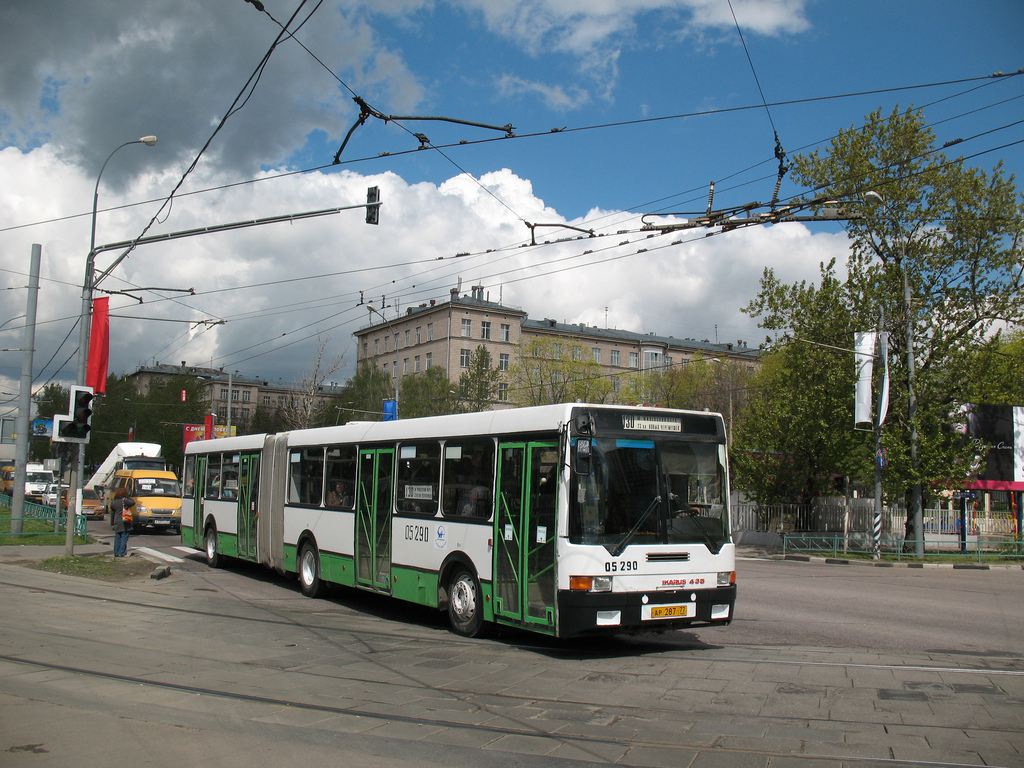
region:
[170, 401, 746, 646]
a long green and white transit bus is driving down the road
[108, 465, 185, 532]
a yellow car is behind the bus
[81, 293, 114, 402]
a red flag is handing off of the pole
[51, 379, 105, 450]
a traffic light is in the shape of an l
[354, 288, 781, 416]
a tan colored building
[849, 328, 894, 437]
a white flag is handing off of the pole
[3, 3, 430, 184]
a blackened storm cloud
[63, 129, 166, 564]
the light pole is off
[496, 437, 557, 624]
the bus door is closed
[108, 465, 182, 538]
A yellow van behind a bus.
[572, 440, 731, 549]
Front windshield of a green and white bus.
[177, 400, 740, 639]
A long white and green bus.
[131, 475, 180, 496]
A windshield on a yellow van.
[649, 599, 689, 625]
Long orange license plate on a bus front.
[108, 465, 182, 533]
A yellow van on the road.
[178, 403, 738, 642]
A long green and white bus.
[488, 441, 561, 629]
First green double doors near the windshield.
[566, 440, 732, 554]
Front windshield of a bus.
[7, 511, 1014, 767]
A grey paved road.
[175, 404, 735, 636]
light green and white bus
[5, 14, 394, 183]
whispy grey clouds in the sky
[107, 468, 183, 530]
bright yellow truck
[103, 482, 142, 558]
woman on the curb holding a purse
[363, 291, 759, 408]
light colored building with many windows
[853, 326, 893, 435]
bright white flag on a pole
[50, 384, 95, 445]
street light with four lights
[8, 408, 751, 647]
line of cars and buses on the street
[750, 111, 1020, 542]
thin tall tree on side of the road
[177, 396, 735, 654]
A green and white bus on the street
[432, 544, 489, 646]
A tire on the bus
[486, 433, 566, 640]
Doors on the bus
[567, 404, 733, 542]
Windshield on the bus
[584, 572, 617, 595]
A headlight on the bus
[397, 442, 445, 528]
A window on the bus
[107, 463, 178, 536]
A yellow van on the street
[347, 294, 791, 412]
A building behind a bus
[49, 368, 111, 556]
A stoplight beside a street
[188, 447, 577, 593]
green and white large bus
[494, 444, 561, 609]
lead glasse door of the bus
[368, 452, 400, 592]
lateral glasse door of the bus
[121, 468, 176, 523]
yellow van on the pavement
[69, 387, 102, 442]
traffict light on the pole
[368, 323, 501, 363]
far beige cream building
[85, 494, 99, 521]
orange car on pavement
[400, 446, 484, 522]
lateral glasses windows of the bus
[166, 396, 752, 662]
A long green and white bus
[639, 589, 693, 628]
A yellow license plate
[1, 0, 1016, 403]
White clouds in the blue sky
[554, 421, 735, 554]
Front window of a bus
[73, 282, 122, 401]
A long red banner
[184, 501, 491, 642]
Three tires of a bus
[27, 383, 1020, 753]
Vehicles on the road.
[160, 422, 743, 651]
A green and white bus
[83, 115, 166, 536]
A street light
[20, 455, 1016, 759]
The road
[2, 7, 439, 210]
A dark grey cloud in the sky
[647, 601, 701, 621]
A yellow and black license plate on the front of a bus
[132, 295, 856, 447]
Light brown bricked buildings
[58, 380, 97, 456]
A black traffic light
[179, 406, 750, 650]
The bus in the road